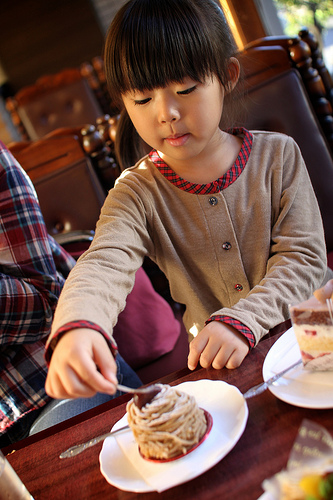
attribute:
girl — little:
[42, 0, 327, 402]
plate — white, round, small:
[98, 377, 248, 493]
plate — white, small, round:
[261, 325, 332, 410]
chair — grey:
[78, 38, 332, 318]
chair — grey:
[15, 125, 122, 241]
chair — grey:
[5, 63, 110, 145]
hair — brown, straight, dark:
[104, 1, 238, 173]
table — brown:
[8, 328, 332, 500]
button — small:
[207, 196, 218, 206]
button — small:
[221, 240, 233, 252]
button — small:
[233, 283, 243, 291]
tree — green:
[271, 0, 332, 51]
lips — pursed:
[162, 131, 189, 149]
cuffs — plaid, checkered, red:
[42, 313, 255, 370]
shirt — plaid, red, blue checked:
[1, 142, 77, 434]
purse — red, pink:
[69, 248, 181, 368]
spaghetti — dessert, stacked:
[125, 380, 207, 460]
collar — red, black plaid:
[148, 125, 253, 193]